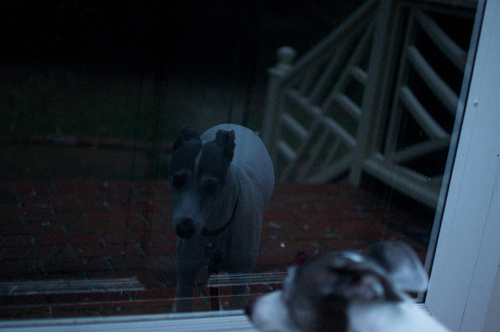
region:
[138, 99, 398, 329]
dog reflection on a door window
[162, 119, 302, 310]
white and brown dog with collar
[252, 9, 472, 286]
white stair railing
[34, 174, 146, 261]
red brick pavement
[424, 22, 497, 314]
white steal door with window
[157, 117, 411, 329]
dog looking at it's reflection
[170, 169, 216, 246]
black noise on a dog face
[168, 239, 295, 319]
white haired legs on a dog body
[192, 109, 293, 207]
white haired back on a dog body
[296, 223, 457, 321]
2 dog brown ears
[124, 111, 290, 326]
one brown white dog looking at reflection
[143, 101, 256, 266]
dog reflected in window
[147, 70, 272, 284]
dog with collar and tag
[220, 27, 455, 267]
hand railing reflected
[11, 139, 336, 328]
brick porch reflected in photo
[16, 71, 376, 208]
grass reflected in window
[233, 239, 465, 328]
dog looking at itself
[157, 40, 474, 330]
white window frame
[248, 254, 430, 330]
back of dogs head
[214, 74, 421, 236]
white railing by brick porch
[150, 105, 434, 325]
Dog looking in a mirror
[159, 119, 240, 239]
Dog does not appear happy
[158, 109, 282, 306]
Brown and white dog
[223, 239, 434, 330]
Dog is looking at it's own reflection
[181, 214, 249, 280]
Dog wearing collar with tags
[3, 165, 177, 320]
Red brick floor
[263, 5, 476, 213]
White wooden stair railing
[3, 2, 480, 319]
Reflection of the room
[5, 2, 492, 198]
Room appears dark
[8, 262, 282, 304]
Glare in the reflection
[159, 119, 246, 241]
the head of a dog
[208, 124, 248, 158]
the ear of a dog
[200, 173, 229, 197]
the eye of a dog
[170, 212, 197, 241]
the nose of a dog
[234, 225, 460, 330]
a white dog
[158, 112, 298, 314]
the reflection of a dog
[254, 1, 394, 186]
a white hand railing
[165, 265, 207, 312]
the leg of a dog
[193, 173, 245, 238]
the collar of a dog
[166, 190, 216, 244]
the snout of a dog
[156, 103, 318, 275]
a dog in the photo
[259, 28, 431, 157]
the side of the stairs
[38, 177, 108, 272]
the brick in the photo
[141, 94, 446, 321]
reflection of the dog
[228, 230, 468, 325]
the regular dog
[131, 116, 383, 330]
a dog looking at himself in reflection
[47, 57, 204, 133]
a green wall in background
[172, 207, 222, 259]
the dogs nose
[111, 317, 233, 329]
the window pane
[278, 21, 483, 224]
the green part of the stair holding